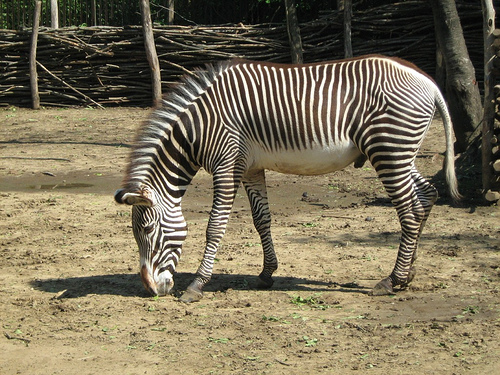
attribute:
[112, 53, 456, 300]
zebra — sniffing , black, white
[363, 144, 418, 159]
stripe — white, brown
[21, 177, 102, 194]
puddle — small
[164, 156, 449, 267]
legs — long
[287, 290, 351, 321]
grass — small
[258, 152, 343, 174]
belly — white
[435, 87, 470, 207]
tail — long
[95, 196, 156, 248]
eye — black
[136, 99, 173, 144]
mane — striped